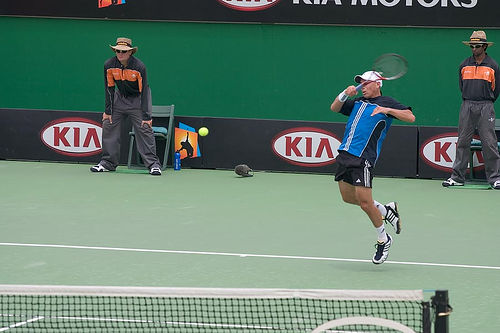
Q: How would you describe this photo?
A: Male person swinging tennis racket.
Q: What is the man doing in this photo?
A: Swinging a tennis racket.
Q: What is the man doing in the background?
A: Standing and watching.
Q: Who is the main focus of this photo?
A: Man with both feet off the ground.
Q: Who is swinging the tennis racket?
A: The male tennis player.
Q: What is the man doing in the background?
A: Leaning on his knees.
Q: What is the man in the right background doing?
A: Standing up straight.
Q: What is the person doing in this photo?
A: Playing tennis.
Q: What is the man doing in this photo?
A: Jumping.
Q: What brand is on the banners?
A: Kia.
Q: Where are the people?
A: Tennis court.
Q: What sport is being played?
A: Tennis.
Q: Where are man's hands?
A: Knees.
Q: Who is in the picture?
A: A player and two men.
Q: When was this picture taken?
A: Daytime.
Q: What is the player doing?
A: Returning a serve.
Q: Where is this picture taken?
A: A tennis court.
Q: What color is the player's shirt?
A: Blue.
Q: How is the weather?
A: Clear.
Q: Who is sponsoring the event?
A: KIA.